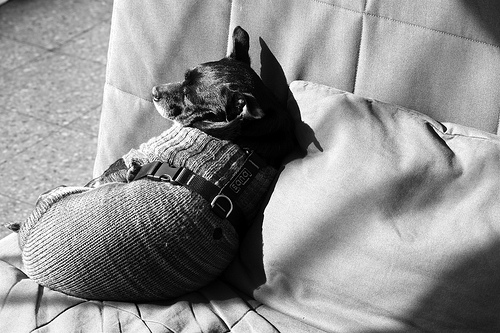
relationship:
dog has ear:
[4, 24, 324, 306] [229, 24, 252, 62]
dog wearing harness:
[4, 24, 324, 306] [96, 150, 240, 225]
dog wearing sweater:
[140, 16, 300, 157] [72, 125, 289, 292]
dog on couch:
[4, 24, 324, 306] [229, 30, 497, 308]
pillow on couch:
[251, 76, 500, 333] [240, 27, 490, 329]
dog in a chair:
[4, 24, 324, 306] [94, 9, 493, 305]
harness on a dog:
[96, 150, 240, 225] [97, 39, 335, 281]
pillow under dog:
[292, 63, 497, 292] [81, 36, 391, 327]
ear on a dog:
[213, 19, 279, 103] [138, 17, 303, 171]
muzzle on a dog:
[138, 73, 178, 113] [113, 30, 313, 197]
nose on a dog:
[140, 71, 202, 120] [141, 33, 331, 201]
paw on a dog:
[89, 148, 154, 209] [121, 20, 301, 186]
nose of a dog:
[140, 71, 202, 120] [156, 25, 302, 179]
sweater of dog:
[88, 22, 447, 318] [42, 53, 302, 297]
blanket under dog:
[97, 24, 483, 266] [33, 50, 302, 249]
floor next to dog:
[5, 20, 119, 226] [20, 47, 314, 282]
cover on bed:
[10, 102, 449, 312] [87, 24, 478, 284]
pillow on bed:
[251, 76, 500, 333] [47, 13, 437, 281]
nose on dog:
[140, 71, 202, 120] [14, 32, 340, 291]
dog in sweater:
[4, 24, 324, 306] [34, 113, 259, 326]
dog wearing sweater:
[14, 32, 340, 291] [30, 120, 252, 315]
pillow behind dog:
[251, 76, 500, 333] [20, 47, 314, 282]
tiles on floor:
[10, 24, 80, 177] [0, 0, 114, 244]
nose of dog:
[140, 71, 202, 120] [20, 47, 314, 282]